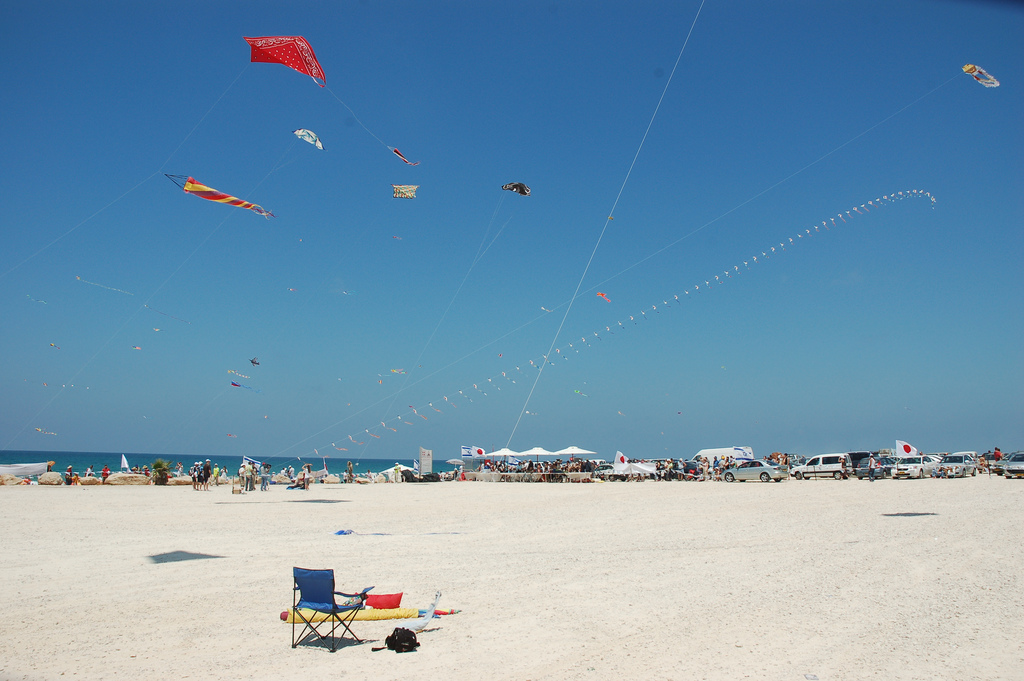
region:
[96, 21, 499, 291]
many kites in sky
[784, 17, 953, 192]
sky is bright blue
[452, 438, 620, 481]
white umbrellas in distance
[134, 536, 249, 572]
kite has shadow on ground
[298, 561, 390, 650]
blue chair on sand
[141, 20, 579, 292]
large kites in the air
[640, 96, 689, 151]
white clouds in blue sky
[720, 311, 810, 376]
white clouds in blue sky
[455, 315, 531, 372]
white clouds in blue sky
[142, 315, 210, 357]
white clouds in blue sky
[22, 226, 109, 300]
white clouds in blue sky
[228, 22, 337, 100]
a red and white kite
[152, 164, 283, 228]
a red and yellow cone shaped kite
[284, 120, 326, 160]
a small white kite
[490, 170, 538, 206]
a small black kite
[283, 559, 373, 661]
a blue folding camping chair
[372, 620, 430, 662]
a black bag or backpack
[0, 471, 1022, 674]
a large white sand beach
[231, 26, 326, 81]
A red kite in the sky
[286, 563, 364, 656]
A blue chair on a beach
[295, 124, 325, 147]
A white kite in the sky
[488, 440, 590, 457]
White umbrellas on a beach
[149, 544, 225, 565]
A kite shadow on a beach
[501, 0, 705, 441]
A long white kite string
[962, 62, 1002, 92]
A white kite in the sky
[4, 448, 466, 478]
A blue strip of ocean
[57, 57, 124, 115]
white clouds in blue sky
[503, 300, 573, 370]
white clouds in blue sky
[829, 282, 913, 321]
white clouds in blue sky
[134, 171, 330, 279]
a kite in the air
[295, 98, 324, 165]
a kite in the air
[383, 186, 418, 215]
a kite in the air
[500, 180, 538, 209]
a kite in the air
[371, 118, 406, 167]
a kite in the air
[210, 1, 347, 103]
a kite in the air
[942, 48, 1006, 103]
a kite in the air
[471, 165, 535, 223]
a kite in the air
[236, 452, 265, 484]
a person on the beach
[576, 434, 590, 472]
a person on the beach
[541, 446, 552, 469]
a person on the beach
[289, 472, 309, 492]
a person on the beach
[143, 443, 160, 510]
a person on the beach